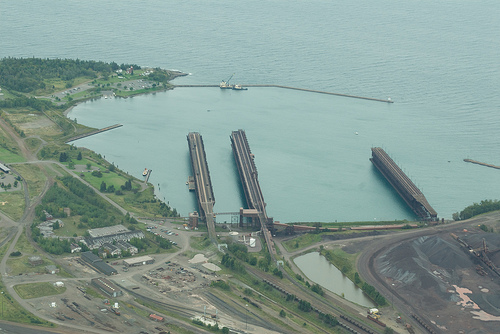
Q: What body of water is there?
A: The ocean.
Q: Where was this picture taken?
A: From the air.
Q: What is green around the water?
A: Trees.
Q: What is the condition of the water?
A: Calm.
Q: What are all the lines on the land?
A: Roads.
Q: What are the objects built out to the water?
A: Runways.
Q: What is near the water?
A: Grove of trees.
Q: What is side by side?
A: Couple of piers.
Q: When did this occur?
A: During the day time.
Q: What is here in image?
A: Highways.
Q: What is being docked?
A: Boats.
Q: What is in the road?
A: Water.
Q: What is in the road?
A: Station.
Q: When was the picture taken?
A: Daytime.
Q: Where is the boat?
A: In the water.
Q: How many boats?
A: One.